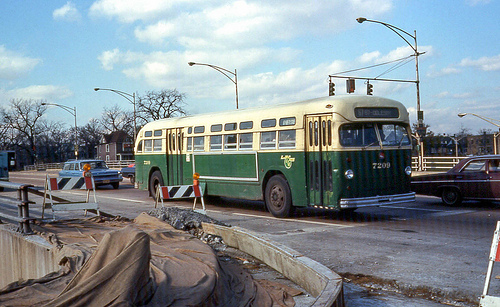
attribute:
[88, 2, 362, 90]
clouds — white , puffy 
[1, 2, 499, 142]
sky — blue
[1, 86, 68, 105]
clouds — white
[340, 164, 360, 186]
headlight — circular 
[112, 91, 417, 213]
bus — green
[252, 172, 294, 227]
tire — white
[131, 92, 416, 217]
bus — green and white, green, white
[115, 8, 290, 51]
clouds — white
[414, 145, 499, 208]
car — black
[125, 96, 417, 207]
bus — white , green 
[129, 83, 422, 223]
bus — big, green, beige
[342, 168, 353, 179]
head light — green 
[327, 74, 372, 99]
traffic lights — lights 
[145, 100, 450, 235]
bus — green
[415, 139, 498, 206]
car — maroon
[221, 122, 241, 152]
window — white